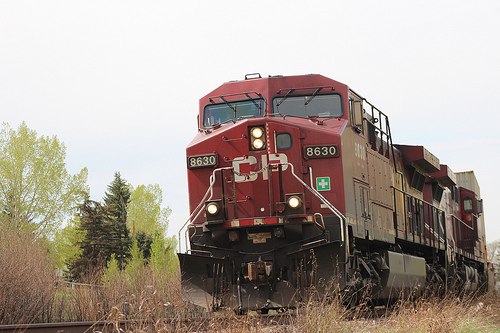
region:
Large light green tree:
[3, 126, 100, 269]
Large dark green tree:
[76, 173, 163, 272]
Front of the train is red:
[173, 70, 384, 292]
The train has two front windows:
[201, 95, 347, 159]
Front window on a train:
[201, 100, 266, 130]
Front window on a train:
[271, 90, 346, 121]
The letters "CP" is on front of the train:
[223, 143, 300, 200]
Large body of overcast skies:
[41, 18, 186, 117]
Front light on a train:
[200, 199, 229, 221]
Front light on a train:
[282, 195, 307, 212]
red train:
[184, 81, 442, 286]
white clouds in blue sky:
[44, 33, 71, 65]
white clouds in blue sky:
[390, 22, 440, 59]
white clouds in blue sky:
[392, 81, 446, 131]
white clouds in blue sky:
[428, 52, 482, 116]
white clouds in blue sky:
[314, 9, 439, 71]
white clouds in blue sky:
[385, 25, 437, 86]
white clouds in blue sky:
[62, 45, 132, 105]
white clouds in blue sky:
[111, 92, 146, 139]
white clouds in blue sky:
[67, 18, 138, 73]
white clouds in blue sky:
[78, 28, 115, 60]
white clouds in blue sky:
[366, 53, 393, 73]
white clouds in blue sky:
[403, 53, 437, 81]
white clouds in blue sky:
[430, 11, 465, 64]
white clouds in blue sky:
[256, 11, 302, 38]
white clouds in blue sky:
[41, 15, 91, 56]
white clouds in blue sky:
[95, 28, 129, 59]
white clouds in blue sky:
[61, 43, 96, 84]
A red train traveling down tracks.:
[176, 73, 494, 315]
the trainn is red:
[338, 164, 354, 187]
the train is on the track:
[222, 301, 287, 326]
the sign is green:
[317, 177, 330, 191]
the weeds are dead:
[306, 301, 332, 323]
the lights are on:
[246, 124, 269, 154]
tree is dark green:
[109, 206, 128, 249]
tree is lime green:
[136, 202, 157, 227]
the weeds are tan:
[122, 276, 164, 311]